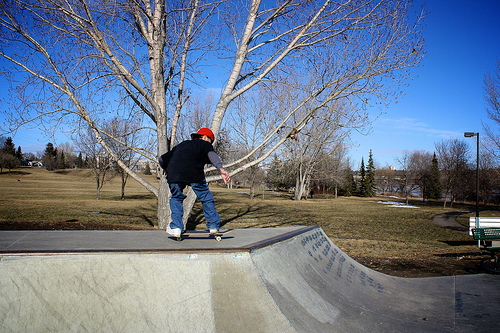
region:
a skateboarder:
[149, 122, 243, 244]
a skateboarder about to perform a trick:
[145, 113, 252, 258]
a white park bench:
[463, 209, 498, 226]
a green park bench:
[468, 226, 498, 266]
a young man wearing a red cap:
[176, 118, 220, 147]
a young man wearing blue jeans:
[164, 175, 226, 224]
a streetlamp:
[447, 125, 499, 214]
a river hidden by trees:
[366, 173, 473, 203]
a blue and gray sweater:
[159, 139, 224, 181]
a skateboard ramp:
[8, 225, 493, 326]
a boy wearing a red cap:
[152, 122, 234, 172]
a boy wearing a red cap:
[116, 75, 259, 239]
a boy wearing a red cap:
[138, 54, 340, 327]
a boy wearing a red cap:
[181, 39, 285, 259]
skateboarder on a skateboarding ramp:
[136, 113, 480, 314]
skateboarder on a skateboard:
[141, 115, 248, 246]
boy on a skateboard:
[133, 109, 241, 246]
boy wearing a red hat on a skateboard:
[143, 107, 246, 251]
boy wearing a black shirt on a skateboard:
[141, 112, 254, 247]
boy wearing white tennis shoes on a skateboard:
[140, 100, 245, 247]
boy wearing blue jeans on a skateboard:
[129, 110, 244, 261]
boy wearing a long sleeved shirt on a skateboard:
[146, 100, 255, 245]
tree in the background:
[61, 12, 338, 136]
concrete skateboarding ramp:
[34, 237, 378, 317]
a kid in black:
[162, 105, 342, 327]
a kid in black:
[153, 94, 265, 265]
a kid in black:
[93, 8, 281, 311]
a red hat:
[181, 120, 235, 147]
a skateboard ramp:
[223, 222, 455, 329]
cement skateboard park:
[10, 195, 491, 330]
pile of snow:
[380, 187, 422, 223]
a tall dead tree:
[1, 0, 408, 221]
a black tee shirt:
[155, 122, 237, 194]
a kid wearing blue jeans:
[148, 176, 253, 274]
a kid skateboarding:
[125, 96, 257, 238]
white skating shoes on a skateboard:
[145, 200, 241, 260]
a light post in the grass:
[458, 88, 485, 249]